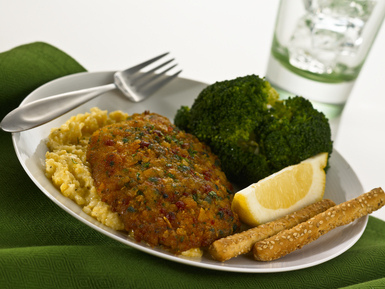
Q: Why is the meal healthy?
A: Vegetables, small meat portion.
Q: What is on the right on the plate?
A: Pretzels.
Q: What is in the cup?
A: Water.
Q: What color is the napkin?
A: Green.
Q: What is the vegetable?
A: Broccoli.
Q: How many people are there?
A: 0.